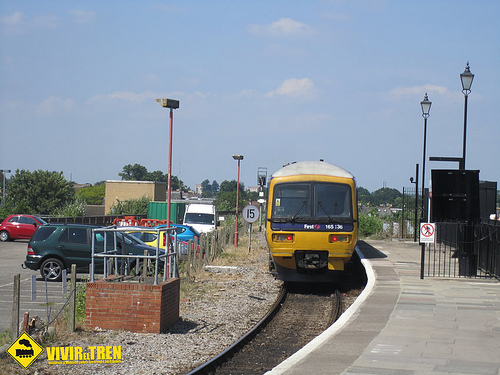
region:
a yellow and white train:
[241, 132, 388, 289]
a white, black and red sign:
[417, 217, 437, 249]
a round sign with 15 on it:
[236, 201, 261, 226]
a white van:
[179, 198, 231, 243]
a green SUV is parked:
[26, 214, 174, 287]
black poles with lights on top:
[408, 55, 489, 261]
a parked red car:
[0, 205, 55, 248]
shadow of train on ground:
[357, 224, 379, 264]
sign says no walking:
[417, 215, 442, 250]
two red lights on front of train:
[287, 232, 338, 245]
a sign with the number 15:
[219, 190, 274, 240]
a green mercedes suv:
[7, 204, 191, 295]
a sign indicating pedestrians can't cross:
[406, 218, 445, 253]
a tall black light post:
[412, 80, 452, 255]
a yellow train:
[254, 140, 397, 306]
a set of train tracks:
[221, 308, 303, 355]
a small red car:
[10, 212, 43, 244]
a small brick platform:
[63, 243, 215, 361]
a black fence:
[432, 208, 495, 302]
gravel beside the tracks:
[195, 280, 265, 342]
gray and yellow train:
[266, 156, 358, 283]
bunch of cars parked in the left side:
[0, 195, 215, 281]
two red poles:
[158, 96, 246, 253]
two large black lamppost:
[419, 58, 474, 268]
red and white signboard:
[419, 223, 434, 243]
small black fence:
[417, 219, 499, 280]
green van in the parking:
[23, 220, 164, 283]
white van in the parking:
[184, 197, 216, 238]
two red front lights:
[272, 232, 354, 244]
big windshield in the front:
[273, 180, 353, 229]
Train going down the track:
[232, 119, 389, 316]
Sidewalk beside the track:
[385, 282, 482, 358]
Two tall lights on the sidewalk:
[387, 45, 492, 201]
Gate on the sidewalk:
[406, 208, 494, 273]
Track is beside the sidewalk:
[219, 275, 359, 373]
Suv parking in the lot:
[27, 218, 187, 295]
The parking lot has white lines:
[9, 276, 66, 352]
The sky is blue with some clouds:
[47, 20, 207, 85]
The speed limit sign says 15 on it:
[237, 178, 261, 277]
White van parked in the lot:
[180, 195, 224, 240]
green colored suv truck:
[25, 218, 210, 293]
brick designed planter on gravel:
[70, 272, 192, 346]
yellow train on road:
[262, 159, 362, 268]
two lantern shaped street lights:
[431, 70, 485, 210]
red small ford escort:
[17, 196, 59, 256]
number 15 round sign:
[220, 192, 292, 242]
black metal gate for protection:
[414, 191, 490, 253]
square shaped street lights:
[151, 91, 256, 180]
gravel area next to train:
[229, 285, 247, 315]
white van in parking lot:
[182, 200, 224, 241]